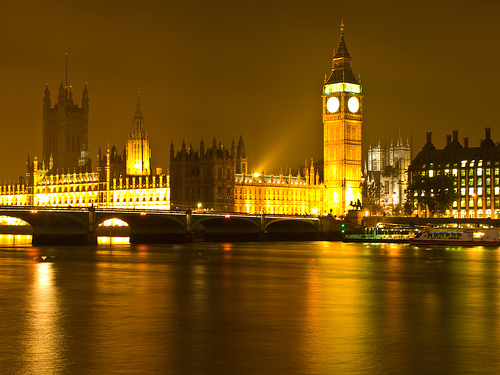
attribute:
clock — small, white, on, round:
[323, 95, 343, 117]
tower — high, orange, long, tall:
[310, 16, 375, 214]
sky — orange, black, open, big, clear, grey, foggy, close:
[1, 5, 499, 168]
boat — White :
[340, 213, 415, 243]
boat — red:
[403, 220, 496, 247]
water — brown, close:
[3, 233, 497, 373]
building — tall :
[32, 62, 101, 185]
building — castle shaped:
[7, 43, 373, 224]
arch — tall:
[33, 168, 201, 273]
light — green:
[313, 174, 481, 275]